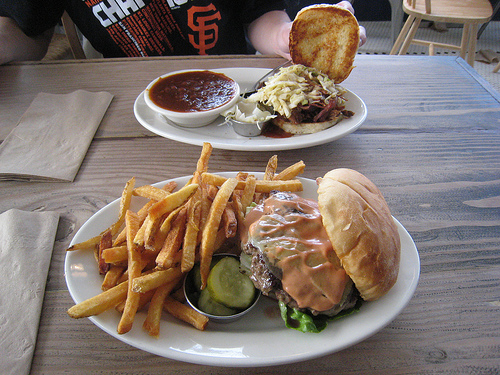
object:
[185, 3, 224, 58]
logo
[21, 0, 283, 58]
shirt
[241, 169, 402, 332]
hamburger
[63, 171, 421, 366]
plate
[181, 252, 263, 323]
cup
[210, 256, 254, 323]
pickles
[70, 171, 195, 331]
fries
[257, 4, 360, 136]
sandwich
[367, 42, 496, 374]
table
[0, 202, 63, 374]
napkin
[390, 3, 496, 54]
chair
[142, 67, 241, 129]
bowl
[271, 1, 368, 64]
hand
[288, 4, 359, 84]
bun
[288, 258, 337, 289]
dressing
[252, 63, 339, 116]
slaw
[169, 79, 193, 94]
beans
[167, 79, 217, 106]
chili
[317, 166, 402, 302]
bun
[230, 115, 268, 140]
cup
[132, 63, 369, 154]
plate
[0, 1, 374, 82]
person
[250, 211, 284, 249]
cheese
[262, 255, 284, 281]
onions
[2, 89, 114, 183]
napkin